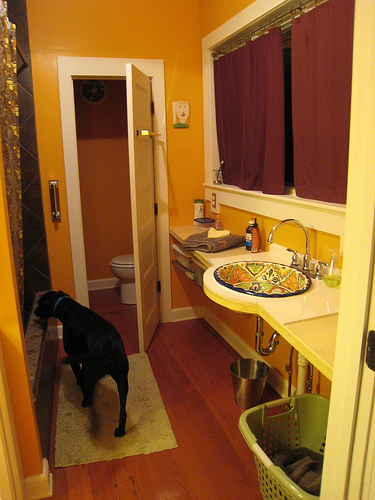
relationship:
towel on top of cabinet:
[187, 232, 225, 252] [297, 327, 338, 345]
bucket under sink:
[228, 359, 268, 397] [225, 268, 302, 297]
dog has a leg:
[39, 292, 125, 387] [76, 383, 92, 412]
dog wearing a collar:
[39, 292, 125, 387] [50, 296, 69, 310]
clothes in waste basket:
[289, 441, 317, 478] [237, 393, 330, 500]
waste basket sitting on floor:
[228, 359, 268, 397] [176, 345, 207, 413]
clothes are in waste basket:
[289, 441, 317, 478] [237, 393, 330, 500]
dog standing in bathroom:
[39, 292, 125, 387] [17, 12, 375, 494]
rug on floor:
[128, 409, 163, 455] [176, 345, 207, 413]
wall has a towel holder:
[136, 21, 183, 52] [46, 176, 62, 227]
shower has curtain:
[19, 76, 37, 299] [0, 34, 18, 242]